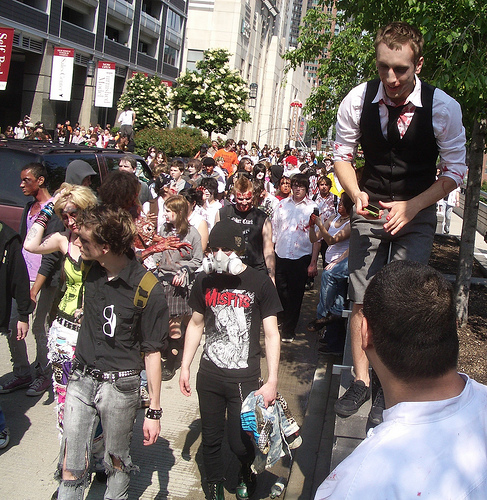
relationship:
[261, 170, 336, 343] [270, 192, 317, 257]
person in shirt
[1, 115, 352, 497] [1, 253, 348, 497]
people on street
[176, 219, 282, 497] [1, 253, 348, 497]
people on street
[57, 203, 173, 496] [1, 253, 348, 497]
man on street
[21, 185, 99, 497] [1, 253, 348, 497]
people on street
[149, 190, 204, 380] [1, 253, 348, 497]
people on street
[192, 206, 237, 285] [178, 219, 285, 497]
mask on people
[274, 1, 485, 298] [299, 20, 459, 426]
tree behind man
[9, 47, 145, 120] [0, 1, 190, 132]
sign hanging from building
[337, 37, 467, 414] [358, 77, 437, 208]
man in a vest